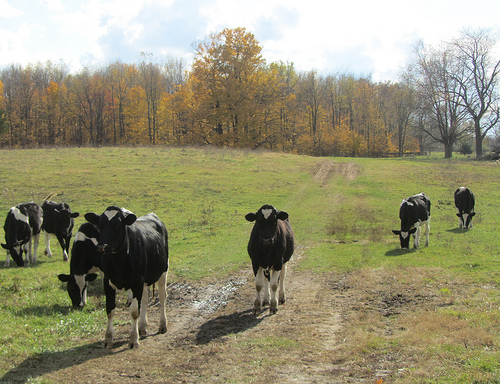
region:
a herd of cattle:
[7, 174, 492, 362]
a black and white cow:
[243, 204, 307, 314]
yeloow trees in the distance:
[178, 32, 405, 149]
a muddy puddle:
[176, 281, 242, 339]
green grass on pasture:
[121, 146, 293, 186]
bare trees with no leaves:
[424, 16, 499, 161]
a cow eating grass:
[391, 191, 439, 253]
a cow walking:
[43, 197, 83, 261]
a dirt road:
[304, 154, 364, 201]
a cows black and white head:
[244, 201, 295, 253]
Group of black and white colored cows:
[0, 180, 498, 353]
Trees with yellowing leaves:
[0, 50, 425, 160]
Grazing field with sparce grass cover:
[0, 145, 498, 381]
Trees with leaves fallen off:
[392, 25, 497, 161]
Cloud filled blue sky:
[0, 3, 498, 83]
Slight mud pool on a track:
[118, 265, 248, 351]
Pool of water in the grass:
[10, 285, 116, 351]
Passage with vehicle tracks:
[66, 146, 367, 381]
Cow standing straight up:
[241, 196, 297, 321]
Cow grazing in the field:
[391, 188, 437, 256]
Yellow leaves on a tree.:
[163, 65, 276, 149]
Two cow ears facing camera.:
[244, 210, 298, 235]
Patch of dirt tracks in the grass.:
[322, 155, 382, 202]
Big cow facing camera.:
[98, 203, 173, 330]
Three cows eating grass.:
[1, 171, 102, 314]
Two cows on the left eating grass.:
[381, 177, 481, 246]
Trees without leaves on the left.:
[413, 67, 493, 144]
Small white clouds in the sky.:
[77, 5, 120, 58]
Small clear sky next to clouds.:
[138, 0, 212, 53]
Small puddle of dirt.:
[206, 273, 227, 320]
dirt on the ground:
[360, 277, 428, 317]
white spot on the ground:
[314, 302, 344, 362]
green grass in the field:
[123, 145, 226, 195]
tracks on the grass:
[294, 145, 374, 186]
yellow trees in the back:
[293, 114, 368, 156]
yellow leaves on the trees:
[326, 133, 336, 145]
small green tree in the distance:
[458, 137, 477, 160]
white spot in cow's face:
[258, 205, 273, 218]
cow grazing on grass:
[378, 170, 439, 267]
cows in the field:
[16, 161, 393, 327]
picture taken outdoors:
[24, 14, 486, 329]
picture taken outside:
[22, 40, 497, 355]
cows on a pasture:
[21, 161, 465, 338]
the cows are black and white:
[22, 156, 494, 349]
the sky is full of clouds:
[94, 26, 193, 53]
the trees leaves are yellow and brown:
[157, 81, 360, 149]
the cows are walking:
[120, 165, 335, 293]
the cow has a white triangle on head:
[256, 205, 278, 220]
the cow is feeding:
[376, 169, 437, 250]